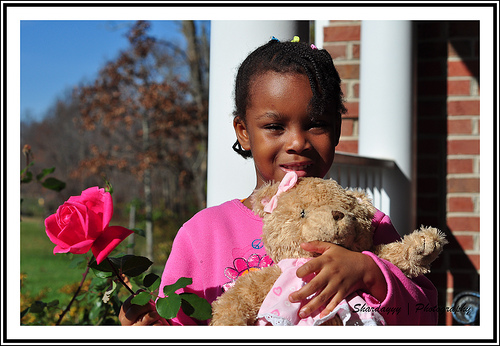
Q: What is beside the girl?
A: A pink flower.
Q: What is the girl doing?
A: Smiling.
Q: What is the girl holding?
A: A toy.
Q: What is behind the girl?
A: A brick wall.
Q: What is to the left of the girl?
A: A pink flower.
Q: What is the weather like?
A: Clear and warm.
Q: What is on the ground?
A: Green grass.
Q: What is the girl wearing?
A: A pink shirt.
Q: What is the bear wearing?
A: A pink outfit.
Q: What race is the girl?
A: Black.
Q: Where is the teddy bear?
A: In the girl's arms.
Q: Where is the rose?
A: By the girl.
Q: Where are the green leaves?
A: By the rose.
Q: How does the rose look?
A: Pink.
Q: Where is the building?
A: Behind the girl.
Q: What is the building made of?
A: Bricks.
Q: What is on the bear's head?
A: Pink bow.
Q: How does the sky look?
A: Clear.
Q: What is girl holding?
A: Bear.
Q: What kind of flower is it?
A: Rose.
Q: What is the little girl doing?
A: Smiling.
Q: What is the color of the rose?
A: Pink.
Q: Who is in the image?
A: Girl with doll.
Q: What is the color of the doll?
A: Brown.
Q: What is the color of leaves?
A: Green.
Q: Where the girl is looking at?
A: To the camera.